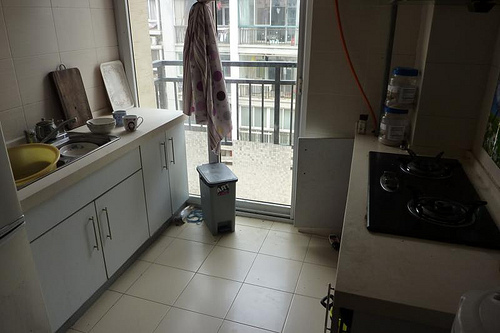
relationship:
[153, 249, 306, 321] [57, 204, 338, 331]
tiles on floor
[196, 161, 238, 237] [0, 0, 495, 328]
trash bin in kitchen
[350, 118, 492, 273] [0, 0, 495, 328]
stove top in kitchen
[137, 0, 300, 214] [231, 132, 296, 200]
door leading patio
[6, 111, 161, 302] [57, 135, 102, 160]
sink full of dishes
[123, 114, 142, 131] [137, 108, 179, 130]
mug on counter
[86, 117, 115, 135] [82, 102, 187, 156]
bowl on counter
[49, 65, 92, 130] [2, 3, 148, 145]
cutting board leaning against wall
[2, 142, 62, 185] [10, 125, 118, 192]
yellow tub in sink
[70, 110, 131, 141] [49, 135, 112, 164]
bowl next to sink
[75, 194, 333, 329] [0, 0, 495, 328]
tile floor in kitchen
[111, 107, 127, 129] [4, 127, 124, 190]
cup next to sink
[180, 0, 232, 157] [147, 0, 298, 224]
towel hanging in front of door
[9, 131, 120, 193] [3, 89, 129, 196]
sink filled with dishes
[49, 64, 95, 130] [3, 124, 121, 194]
cutting board near sink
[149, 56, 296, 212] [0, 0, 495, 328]
deck outside of kitchen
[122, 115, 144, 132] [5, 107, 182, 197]
mug on top of counter